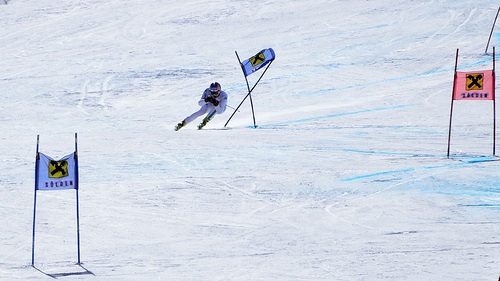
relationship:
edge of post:
[235, 51, 241, 58] [231, 49, 260, 129]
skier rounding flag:
[173, 82, 235, 135] [237, 43, 278, 83]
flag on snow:
[237, 43, 278, 83] [144, 6, 286, 138]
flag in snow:
[450, 67, 493, 104] [277, 3, 499, 109]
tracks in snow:
[403, 5, 484, 54] [277, 3, 499, 109]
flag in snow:
[237, 43, 278, 83] [144, 6, 286, 138]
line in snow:
[301, 57, 499, 99] [277, 3, 499, 109]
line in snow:
[258, 99, 432, 131] [277, 3, 499, 109]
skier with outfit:
[173, 82, 235, 135] [185, 90, 231, 128]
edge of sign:
[67, 150, 78, 161] [30, 149, 87, 194]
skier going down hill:
[173, 82, 235, 135] [1, 1, 498, 280]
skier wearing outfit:
[173, 82, 235, 135] [185, 90, 231, 128]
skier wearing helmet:
[173, 82, 235, 135] [207, 80, 224, 93]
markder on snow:
[218, 38, 288, 133] [144, 6, 286, 138]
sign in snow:
[30, 149, 87, 194] [2, 4, 162, 268]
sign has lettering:
[30, 149, 87, 194] [42, 181, 76, 189]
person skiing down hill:
[173, 82, 235, 135] [1, 1, 498, 280]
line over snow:
[301, 57, 499, 99] [277, 3, 499, 109]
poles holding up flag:
[225, 51, 274, 130] [237, 43, 278, 83]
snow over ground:
[277, 3, 499, 109] [2, 4, 496, 280]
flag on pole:
[450, 67, 493, 104] [445, 47, 468, 161]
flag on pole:
[450, 67, 493, 104] [487, 45, 499, 158]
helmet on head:
[207, 80, 224, 93] [207, 81, 223, 101]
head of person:
[207, 81, 223, 101] [173, 82, 235, 135]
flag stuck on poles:
[237, 43, 278, 83] [225, 51, 274, 130]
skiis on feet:
[175, 126, 210, 132] [175, 122, 205, 132]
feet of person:
[175, 122, 205, 132] [173, 82, 235, 135]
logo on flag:
[249, 54, 271, 66] [237, 43, 278, 83]